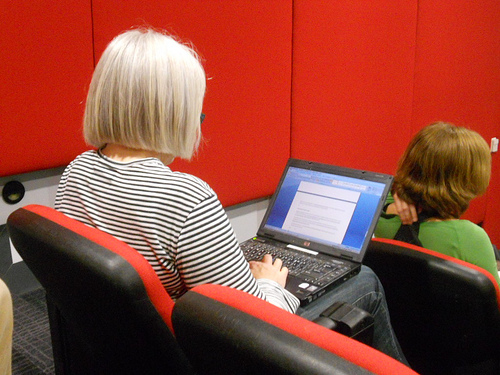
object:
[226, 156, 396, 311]
computer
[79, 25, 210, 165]
hair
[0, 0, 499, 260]
wall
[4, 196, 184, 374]
seat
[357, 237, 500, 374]
back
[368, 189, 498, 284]
shirt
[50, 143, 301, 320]
shirt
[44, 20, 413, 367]
woman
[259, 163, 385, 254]
screen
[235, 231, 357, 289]
keyboard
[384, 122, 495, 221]
hair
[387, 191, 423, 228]
hand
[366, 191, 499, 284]
back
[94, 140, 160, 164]
neck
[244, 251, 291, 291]
hand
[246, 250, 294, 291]
trackpad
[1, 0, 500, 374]
room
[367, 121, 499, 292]
woman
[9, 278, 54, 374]
floor